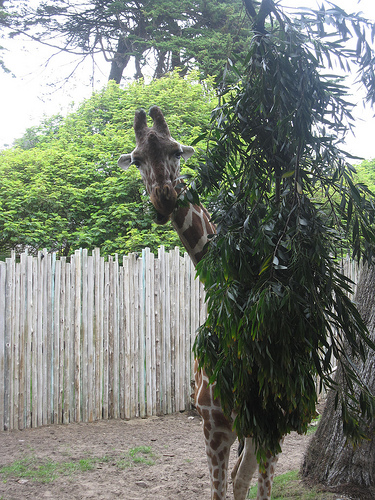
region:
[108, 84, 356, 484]
a tall giraffe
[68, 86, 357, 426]
a tall giraffe standing up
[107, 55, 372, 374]
a tall giraffe eating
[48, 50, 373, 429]
a tall giraffe eating leaves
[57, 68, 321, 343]
a tall giraffe eating leaves on the tree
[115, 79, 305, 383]
a giraffe eating green leaves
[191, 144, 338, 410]
green leaves on a tree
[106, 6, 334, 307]
a tree branch hanging down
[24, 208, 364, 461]
a tall wooden fence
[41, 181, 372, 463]
a giraffe in a fenced in area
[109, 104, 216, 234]
the head of a giraffe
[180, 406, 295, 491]
the legs of a giraffe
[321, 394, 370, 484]
the bark of a tree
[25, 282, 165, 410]
a fence made out of trees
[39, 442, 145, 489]
the ground in the giraffe enclosure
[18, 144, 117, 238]
the green leaves of some trees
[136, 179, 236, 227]
leaves being eaten by a giraffe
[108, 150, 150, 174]
the ear of a giraffe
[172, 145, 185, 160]
a giraffe's eye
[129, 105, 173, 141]
two horns on the top of a giraffe's head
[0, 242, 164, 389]
A fence is in the background.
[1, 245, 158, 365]
The fence is made of wood.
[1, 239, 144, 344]
The wood is brown.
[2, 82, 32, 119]
The sky is white.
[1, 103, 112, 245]
The trees have leaves.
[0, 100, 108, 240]
Trees are in the background.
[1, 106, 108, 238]
The trees are green.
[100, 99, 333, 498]
A giraffe is behind the branch.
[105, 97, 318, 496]
The giraffe is brown and white.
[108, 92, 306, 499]
The giraffe is tall.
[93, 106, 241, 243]
an adult giraffe eating leaves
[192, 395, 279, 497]
the legs of an adult giraffe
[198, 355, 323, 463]
hanging green foliage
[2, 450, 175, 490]
a thin strip of patchy green grass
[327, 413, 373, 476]
the thick brown bark of a tree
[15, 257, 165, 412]
asymmetrical logs comprising a fence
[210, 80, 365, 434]
low hanging tree branches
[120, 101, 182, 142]
two antlers on a giraffe's head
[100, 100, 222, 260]
a giraffe's face looking at the camera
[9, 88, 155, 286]
a lush wide green tree in the background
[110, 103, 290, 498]
The giraffe is standing.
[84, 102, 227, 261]
The giraffe has eyes.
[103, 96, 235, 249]
Giraffe's eyes are open.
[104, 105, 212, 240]
Giraffe looking into camera.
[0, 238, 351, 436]
The fence is wood.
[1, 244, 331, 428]
Fence slats are uneven.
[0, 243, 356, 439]
The fence is unpainted.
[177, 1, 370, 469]
Tree limb is hanging down.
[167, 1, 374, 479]
Tree limb is green.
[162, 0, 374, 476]
Tree limb is leafy.